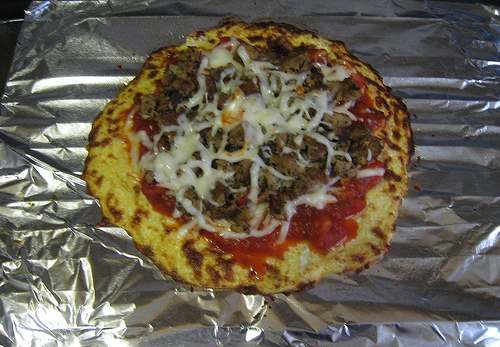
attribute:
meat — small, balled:
[341, 125, 371, 145]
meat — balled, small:
[165, 52, 197, 79]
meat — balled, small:
[257, 187, 293, 219]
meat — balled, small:
[278, 47, 313, 76]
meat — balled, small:
[324, 75, 357, 100]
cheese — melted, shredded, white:
[225, 95, 289, 139]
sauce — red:
[132, 187, 182, 219]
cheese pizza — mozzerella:
[26, 18, 423, 334]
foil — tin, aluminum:
[14, 9, 485, 345]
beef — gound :
[285, 40, 310, 62]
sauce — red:
[300, 214, 347, 242]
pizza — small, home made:
[87, 17, 412, 289]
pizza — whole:
[64, 10, 429, 297]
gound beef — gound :
[290, 125, 345, 175]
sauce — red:
[110, 103, 162, 132]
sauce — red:
[181, 55, 386, 245]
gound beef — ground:
[140, 167, 159, 187]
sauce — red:
[297, 204, 353, 241]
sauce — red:
[294, 204, 360, 256]